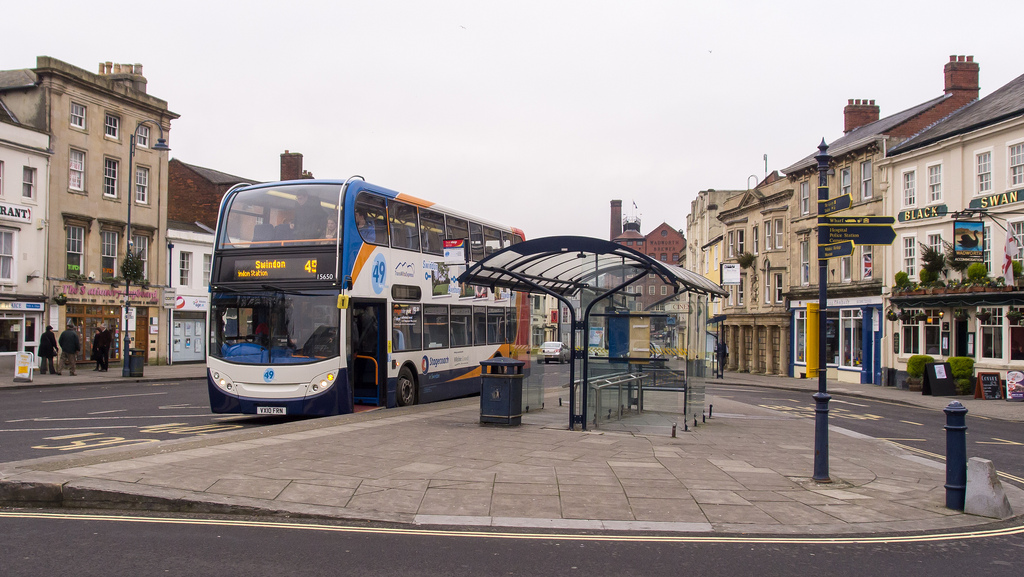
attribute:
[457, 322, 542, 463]
bin — blue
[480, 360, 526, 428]
garbage can — blue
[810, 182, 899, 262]
street sign — blue and yellow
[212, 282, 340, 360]
bus-front window — driver's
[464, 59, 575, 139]
thick clouds — in sky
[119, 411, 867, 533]
bus stop — brown stone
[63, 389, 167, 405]
white lines — on road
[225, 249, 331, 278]
orange lcd — with destination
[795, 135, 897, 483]
black pole — with signs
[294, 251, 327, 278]
orange-bus numbers — lit up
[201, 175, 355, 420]
bus front — blue and white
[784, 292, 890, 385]
building paint — blue and white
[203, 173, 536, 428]
touring bus — double decker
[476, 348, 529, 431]
receptacle — for trash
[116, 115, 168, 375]
street light — high, goose neck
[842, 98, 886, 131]
chimney — wide, red, brick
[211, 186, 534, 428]
bus — double decker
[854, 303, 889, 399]
trim — blue